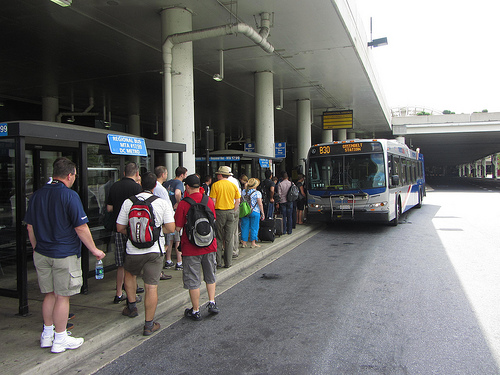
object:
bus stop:
[0, 119, 187, 319]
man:
[24, 155, 107, 355]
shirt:
[25, 177, 95, 260]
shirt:
[115, 190, 175, 255]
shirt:
[238, 189, 262, 217]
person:
[115, 163, 177, 337]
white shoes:
[40, 328, 53, 348]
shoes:
[50, 334, 85, 353]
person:
[254, 166, 276, 219]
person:
[273, 170, 298, 235]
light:
[364, 37, 389, 49]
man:
[208, 165, 240, 271]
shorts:
[114, 230, 129, 269]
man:
[104, 161, 140, 303]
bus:
[301, 136, 426, 226]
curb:
[11, 222, 319, 374]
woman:
[238, 176, 266, 249]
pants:
[241, 212, 261, 243]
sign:
[105, 134, 150, 159]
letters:
[124, 148, 132, 156]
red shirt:
[174, 191, 219, 258]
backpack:
[181, 195, 218, 250]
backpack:
[125, 193, 163, 252]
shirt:
[207, 177, 244, 211]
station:
[1, 1, 499, 375]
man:
[176, 174, 223, 320]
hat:
[180, 174, 203, 187]